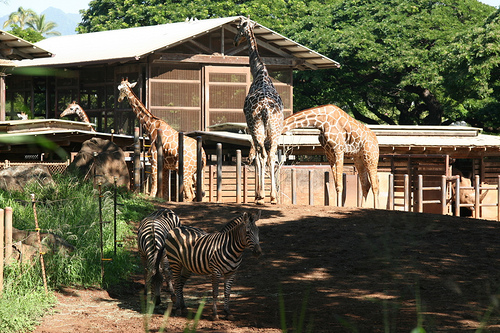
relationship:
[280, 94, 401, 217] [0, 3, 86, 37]
giraffe in sun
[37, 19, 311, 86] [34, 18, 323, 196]
roof of building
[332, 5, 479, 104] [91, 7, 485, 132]
trees in background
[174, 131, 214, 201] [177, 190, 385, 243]
pole in ground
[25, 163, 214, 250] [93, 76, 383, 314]
fence between animals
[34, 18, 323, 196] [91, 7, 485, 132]
building in background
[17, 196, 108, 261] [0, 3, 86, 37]
grass in sun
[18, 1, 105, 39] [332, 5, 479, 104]
sky behind trees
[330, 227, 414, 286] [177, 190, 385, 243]
dirt on ground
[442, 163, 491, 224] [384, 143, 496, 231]
rhinoceros in pen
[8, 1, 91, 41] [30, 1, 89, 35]
range of mountains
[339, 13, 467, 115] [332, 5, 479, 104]
group of trees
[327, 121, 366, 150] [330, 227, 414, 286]
fur has dirt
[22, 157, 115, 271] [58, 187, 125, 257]
section of grass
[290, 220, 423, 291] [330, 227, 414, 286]
patch of dirt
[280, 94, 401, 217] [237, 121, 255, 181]
giraffe has head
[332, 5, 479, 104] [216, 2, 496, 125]
trees of tree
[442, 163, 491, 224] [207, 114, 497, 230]
rhinoceros in barn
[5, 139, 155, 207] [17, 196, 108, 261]
rocks in grass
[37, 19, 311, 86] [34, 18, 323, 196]
roof of barn